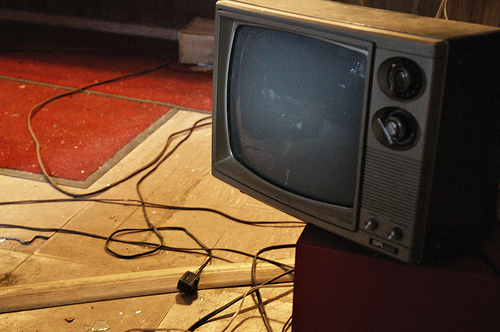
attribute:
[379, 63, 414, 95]
knob — black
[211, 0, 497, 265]
tv — has, black, standard definition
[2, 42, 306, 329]
wire — brown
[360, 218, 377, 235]
knob — silver 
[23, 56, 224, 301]
cord — black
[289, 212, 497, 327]
stand — plum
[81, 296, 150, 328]
glass — Broken 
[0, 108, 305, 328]
wood flooring — light colored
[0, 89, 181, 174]
rug — red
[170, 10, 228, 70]
box — cardboard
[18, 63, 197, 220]
rug — red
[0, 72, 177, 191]
carpet — red 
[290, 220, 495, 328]
table — cube 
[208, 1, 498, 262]
television — gray , Old , dirty , silver , small, metal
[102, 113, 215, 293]
cord — brown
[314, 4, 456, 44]
dust — on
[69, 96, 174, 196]
trim — gray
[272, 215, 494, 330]
table — wooden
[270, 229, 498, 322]
table — wooden